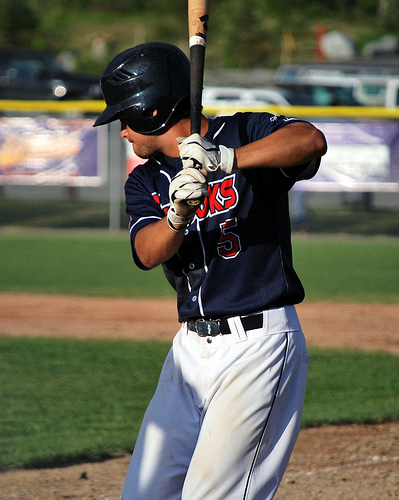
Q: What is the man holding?
A: A bat.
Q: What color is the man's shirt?
A: Blue.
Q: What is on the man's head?
A: A helmet.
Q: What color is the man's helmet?
A: Black.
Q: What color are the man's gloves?
A: White.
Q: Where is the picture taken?
A: A baseball field.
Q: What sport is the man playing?
A: Baseball.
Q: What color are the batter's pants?
A: White.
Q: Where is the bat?
A: In player's hands.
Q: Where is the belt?
A: Around player's waist.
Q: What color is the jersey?
A: Dark blue.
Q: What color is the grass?
A: Green.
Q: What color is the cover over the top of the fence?
A: Yellow.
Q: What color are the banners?
A: Purple.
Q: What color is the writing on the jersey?
A: Red.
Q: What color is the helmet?
A: Black.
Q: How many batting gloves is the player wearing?
A: 2.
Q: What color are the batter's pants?
A: White.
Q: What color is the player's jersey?
A: Dark blue.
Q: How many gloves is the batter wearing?
A: 2.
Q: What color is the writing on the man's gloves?
A: White.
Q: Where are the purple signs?
A: On the fence.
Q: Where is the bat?
A: Player's hands.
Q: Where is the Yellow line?
A: Top of fence.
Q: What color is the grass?
A: Green.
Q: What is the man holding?
A: A baseball bat.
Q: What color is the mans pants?
A: White.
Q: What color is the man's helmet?
A: Black.